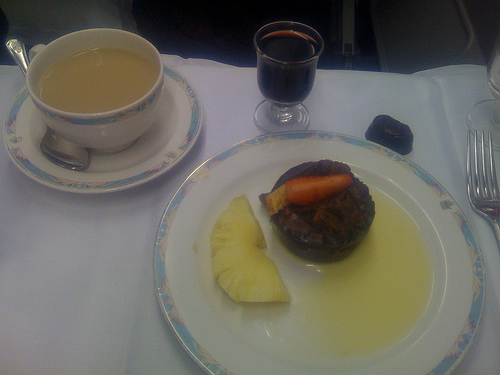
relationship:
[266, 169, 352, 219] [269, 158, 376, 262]
carrot on top of meat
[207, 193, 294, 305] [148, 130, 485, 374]
pineapple on top of plate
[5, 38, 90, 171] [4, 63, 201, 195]
spoon on top of saucer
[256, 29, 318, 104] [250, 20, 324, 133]
liquid inside of glass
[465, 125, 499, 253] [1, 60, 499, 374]
fork on top of tablecloth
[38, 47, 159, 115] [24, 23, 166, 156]
gravy inside of cup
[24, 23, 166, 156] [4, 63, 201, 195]
cup on top of saucer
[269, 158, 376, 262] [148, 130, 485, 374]
meat on top of plate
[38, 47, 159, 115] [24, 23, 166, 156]
gravy inside cup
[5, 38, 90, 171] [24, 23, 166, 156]
spoon next to cup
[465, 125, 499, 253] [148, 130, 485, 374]
fork next to plate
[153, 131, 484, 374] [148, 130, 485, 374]
design on edge of plate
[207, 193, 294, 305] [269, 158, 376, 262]
pineapple on side of meat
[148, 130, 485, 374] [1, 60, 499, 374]
plate on top of tablecloth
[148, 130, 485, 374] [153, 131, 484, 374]
plate has design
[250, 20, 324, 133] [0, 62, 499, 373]
glass on top of table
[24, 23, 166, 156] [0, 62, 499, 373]
cup on top of table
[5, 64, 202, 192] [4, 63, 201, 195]
trim around saucer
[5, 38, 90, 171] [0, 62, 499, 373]
spoon on top of table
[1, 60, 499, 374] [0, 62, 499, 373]
tablecloth on top of table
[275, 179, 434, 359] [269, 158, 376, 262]
sauce underneath meat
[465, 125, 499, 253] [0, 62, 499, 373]
fork on top of table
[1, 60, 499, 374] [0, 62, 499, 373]
tablecloth covering table